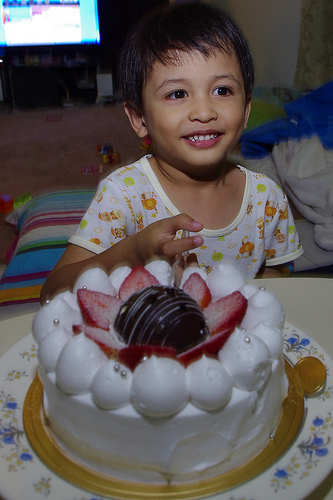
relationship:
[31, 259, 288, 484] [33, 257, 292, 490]
icing on cake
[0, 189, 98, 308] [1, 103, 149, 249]
pillow on floor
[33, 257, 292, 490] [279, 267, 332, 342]
cake on table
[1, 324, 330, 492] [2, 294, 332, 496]
blue flowers on plate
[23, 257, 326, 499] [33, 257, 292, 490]
cake on cake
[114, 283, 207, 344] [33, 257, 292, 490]
ball of cake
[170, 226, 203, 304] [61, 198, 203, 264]
knife in hand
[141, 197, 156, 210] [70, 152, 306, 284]
design on shirt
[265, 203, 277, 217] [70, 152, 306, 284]
design on shirt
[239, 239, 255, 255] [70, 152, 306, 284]
design on shirt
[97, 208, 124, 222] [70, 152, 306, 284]
design on shirt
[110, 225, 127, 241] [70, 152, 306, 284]
design on shirt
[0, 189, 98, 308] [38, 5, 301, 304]
pillow behind boy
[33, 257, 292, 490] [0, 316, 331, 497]
cake sitting on plate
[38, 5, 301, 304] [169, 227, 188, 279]
boy holding knife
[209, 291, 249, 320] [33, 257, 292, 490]
strawberries on cake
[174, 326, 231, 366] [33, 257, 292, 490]
strawberry on cake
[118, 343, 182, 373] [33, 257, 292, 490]
strawberry on cake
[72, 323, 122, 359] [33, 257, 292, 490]
strawberry on cake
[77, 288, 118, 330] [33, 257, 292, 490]
strawberries on cake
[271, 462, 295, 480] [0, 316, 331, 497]
flower on plate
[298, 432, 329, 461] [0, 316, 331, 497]
flower on plate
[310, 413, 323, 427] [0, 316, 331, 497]
flower on plate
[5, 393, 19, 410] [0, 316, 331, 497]
flower on plate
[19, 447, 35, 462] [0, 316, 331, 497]
flower on plate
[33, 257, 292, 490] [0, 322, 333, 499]
cake sitting on cake tray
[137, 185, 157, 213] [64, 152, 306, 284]
shirt mushrooms sitting on shirt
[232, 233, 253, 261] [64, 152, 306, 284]
shirt mushrooms sitting on shirt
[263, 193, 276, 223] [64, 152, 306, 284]
shirt mushrooms sitting on shirt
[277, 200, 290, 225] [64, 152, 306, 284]
shirt mushrooms sitting on shirt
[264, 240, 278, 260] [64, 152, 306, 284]
shirt mushrooms sitting on shirt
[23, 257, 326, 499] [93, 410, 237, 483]
cake with icing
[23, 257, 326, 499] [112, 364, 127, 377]
cake with beads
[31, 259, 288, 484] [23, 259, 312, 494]
icing on cake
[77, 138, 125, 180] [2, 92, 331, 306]
toys on floor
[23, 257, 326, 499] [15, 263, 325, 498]
cake on cake tray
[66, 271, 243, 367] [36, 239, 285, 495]
strawberries on cake